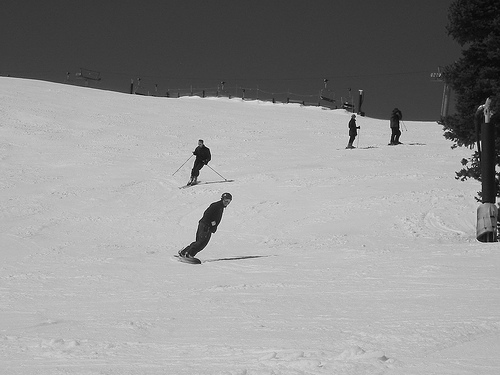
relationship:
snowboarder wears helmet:
[178, 192, 233, 262] [221, 190, 232, 197]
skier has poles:
[341, 116, 366, 150] [346, 129, 356, 149]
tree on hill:
[440, 5, 499, 204] [1, 79, 499, 375]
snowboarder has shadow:
[178, 192, 233, 262] [202, 253, 267, 260]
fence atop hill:
[119, 76, 345, 110] [1, 79, 499, 375]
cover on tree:
[470, 104, 500, 241] [440, 5, 499, 204]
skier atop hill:
[341, 116, 366, 150] [1, 79, 499, 375]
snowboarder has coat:
[178, 192, 233, 262] [200, 198, 225, 224]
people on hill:
[172, 109, 403, 258] [1, 79, 499, 375]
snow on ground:
[4, 81, 182, 375] [1, 79, 499, 375]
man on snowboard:
[179, 192, 235, 265] [179, 251, 202, 262]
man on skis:
[168, 141, 232, 189] [165, 150, 231, 181]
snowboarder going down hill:
[178, 192, 233, 262] [1, 79, 499, 375]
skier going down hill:
[341, 116, 366, 150] [1, 79, 499, 375]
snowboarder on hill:
[178, 192, 233, 262] [1, 79, 499, 375]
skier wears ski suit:
[341, 116, 366, 150] [345, 121, 358, 146]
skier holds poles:
[341, 116, 366, 150] [346, 129, 356, 149]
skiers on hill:
[173, 114, 363, 193] [1, 79, 499, 375]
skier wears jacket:
[341, 116, 366, 150] [348, 117, 358, 135]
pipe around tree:
[470, 104, 500, 241] [440, 5, 499, 204]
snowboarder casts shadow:
[178, 192, 233, 262] [202, 253, 267, 260]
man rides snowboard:
[179, 192, 235, 265] [179, 251, 202, 262]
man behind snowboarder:
[168, 141, 232, 189] [178, 192, 233, 262]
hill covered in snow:
[1, 79, 499, 375] [4, 81, 182, 375]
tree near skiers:
[440, 5, 499, 204] [173, 114, 363, 193]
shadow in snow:
[202, 253, 267, 260] [4, 81, 182, 375]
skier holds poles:
[168, 141, 232, 189] [165, 150, 231, 181]